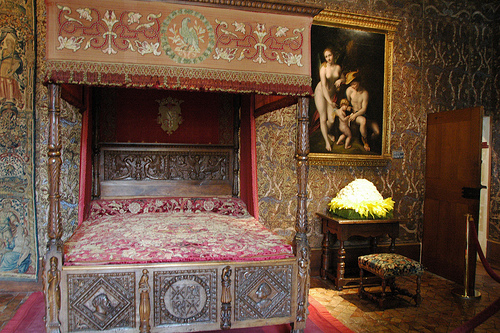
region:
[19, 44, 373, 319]
picture is taken indoors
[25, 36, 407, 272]
the bed is very old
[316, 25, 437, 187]
a picture is on the wall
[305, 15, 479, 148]
the wall paper is ornate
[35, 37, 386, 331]
the bedroom is old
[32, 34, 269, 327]
the bed frame is wood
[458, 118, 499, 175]
the door is open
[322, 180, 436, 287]
the table is made of wood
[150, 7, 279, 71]
a round emblem is on the bed frame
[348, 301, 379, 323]
the floor is tile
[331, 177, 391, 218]
yellow floral arrangement on side table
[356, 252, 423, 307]
floral stool on the floor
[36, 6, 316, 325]
ornate canopy bed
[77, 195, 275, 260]
red patterned bedspread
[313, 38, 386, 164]
painting of three nude people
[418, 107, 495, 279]
open brown door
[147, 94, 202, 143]
decoration on headboard of bed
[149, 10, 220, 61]
green bird surrounded by green circle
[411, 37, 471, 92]
gold patterned wallpaper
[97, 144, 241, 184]
ornate wooden carving on headboard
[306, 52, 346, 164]
Lady with no clothes on in portrait.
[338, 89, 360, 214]
Naked child in portrait on wall.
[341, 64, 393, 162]
Person with only a hat on in portrait.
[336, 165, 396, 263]
Flowers under portrait on wall.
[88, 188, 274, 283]
Red and white bedspread.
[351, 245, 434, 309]
Multi colored stool near flowers.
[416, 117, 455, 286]
Wood door is open.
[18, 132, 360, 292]
Wood posts on bed are dark brown.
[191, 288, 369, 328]
Red accent rug on floor.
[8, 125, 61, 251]
Wall has many colors on it.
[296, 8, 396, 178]
Antique painting of nude figures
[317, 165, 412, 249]
Large spray of yellow flowers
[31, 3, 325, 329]
Red and brown bed canopy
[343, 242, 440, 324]
Floral upholstery wooden stool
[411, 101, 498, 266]
Brown open wooden door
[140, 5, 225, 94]
Bird design on bed canopy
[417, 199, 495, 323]
Red velvet rope with brass runners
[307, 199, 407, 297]
Wooden bedside table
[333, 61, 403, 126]
Brown hat on painted figure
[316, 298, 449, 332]
geometric tan designed floor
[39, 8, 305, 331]
an old style bed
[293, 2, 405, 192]
a picture of a naked family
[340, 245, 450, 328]
a wooden stool with fabric covering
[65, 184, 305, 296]
red bed set cover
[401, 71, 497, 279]
a wooden door open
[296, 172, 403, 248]
a plant on the table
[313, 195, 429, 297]
a wooden table in front of a stool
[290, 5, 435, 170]
a picture in a gold frame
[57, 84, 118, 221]
red curtains on the bed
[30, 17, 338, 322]
a wooden bed